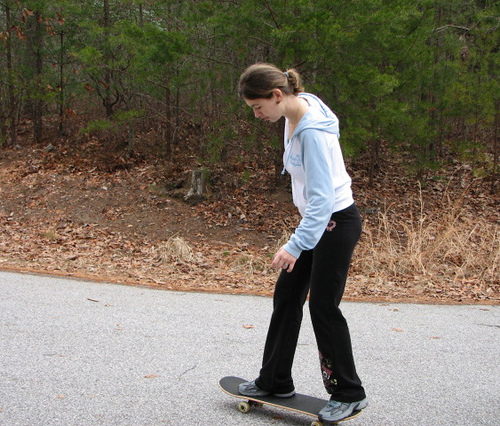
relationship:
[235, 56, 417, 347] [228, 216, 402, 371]
girl wearing pants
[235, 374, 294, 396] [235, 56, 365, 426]
right shoe on girl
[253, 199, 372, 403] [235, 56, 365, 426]
pants of girl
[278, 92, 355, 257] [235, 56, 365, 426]
jacket on girl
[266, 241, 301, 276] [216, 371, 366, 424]
hand of skater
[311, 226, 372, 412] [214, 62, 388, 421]
leg of skater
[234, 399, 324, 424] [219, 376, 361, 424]
wheels on skateboard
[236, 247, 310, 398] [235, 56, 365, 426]
leg of girl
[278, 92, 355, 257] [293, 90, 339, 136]
jacket has hood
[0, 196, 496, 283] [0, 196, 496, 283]
grass behind grass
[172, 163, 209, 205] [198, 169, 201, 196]
stump with mold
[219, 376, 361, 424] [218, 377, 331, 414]
skateboard with paper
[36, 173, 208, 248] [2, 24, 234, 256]
dirt inside forest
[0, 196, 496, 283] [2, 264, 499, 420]
grass skateboarding in street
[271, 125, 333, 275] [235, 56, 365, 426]
arm on girl